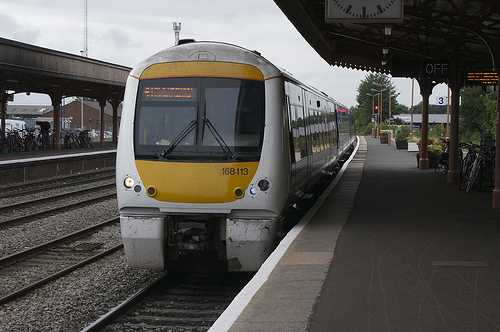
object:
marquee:
[141, 85, 198, 101]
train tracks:
[107, 274, 216, 326]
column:
[417, 75, 432, 166]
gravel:
[105, 275, 114, 280]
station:
[206, 0, 499, 331]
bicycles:
[81, 132, 96, 149]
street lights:
[374, 82, 380, 85]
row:
[364, 87, 394, 144]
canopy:
[0, 36, 135, 86]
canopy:
[273, 0, 498, 82]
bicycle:
[459, 140, 486, 194]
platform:
[203, 135, 497, 330]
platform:
[1, 134, 115, 188]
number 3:
[438, 97, 442, 104]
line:
[206, 132, 361, 329]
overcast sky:
[2, 2, 451, 102]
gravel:
[71, 288, 81, 296]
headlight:
[122, 175, 134, 188]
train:
[115, 40, 356, 271]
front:
[113, 44, 285, 271]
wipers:
[203, 118, 235, 156]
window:
[202, 77, 265, 155]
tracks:
[2, 214, 122, 302]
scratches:
[365, 208, 499, 329]